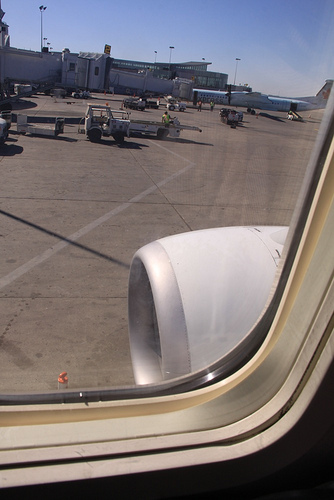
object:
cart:
[13, 110, 68, 139]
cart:
[123, 97, 145, 112]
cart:
[147, 97, 160, 107]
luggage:
[220, 108, 228, 116]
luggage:
[148, 98, 157, 104]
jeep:
[82, 104, 130, 147]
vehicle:
[70, 89, 89, 98]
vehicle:
[0, 111, 9, 149]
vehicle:
[220, 108, 244, 129]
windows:
[201, 94, 202, 96]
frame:
[129, 237, 183, 383]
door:
[289, 101, 297, 113]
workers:
[210, 99, 215, 111]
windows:
[95, 66, 100, 76]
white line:
[155, 140, 194, 164]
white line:
[79, 165, 195, 237]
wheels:
[111, 129, 124, 143]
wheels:
[88, 127, 103, 142]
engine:
[124, 224, 295, 407]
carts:
[166, 96, 188, 112]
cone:
[58, 370, 68, 389]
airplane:
[192, 77, 332, 121]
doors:
[193, 90, 198, 104]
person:
[162, 111, 172, 125]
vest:
[162, 114, 169, 123]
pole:
[38, 13, 43, 51]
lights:
[38, 4, 44, 12]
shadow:
[81, 245, 131, 270]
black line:
[8, 211, 49, 234]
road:
[6, 87, 315, 219]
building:
[79, 50, 105, 90]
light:
[106, 102, 108, 106]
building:
[3, 44, 58, 84]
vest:
[198, 101, 202, 105]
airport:
[0, 37, 316, 146]